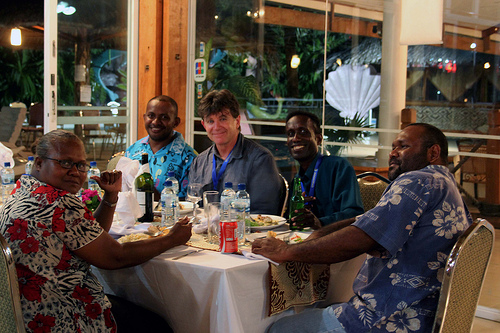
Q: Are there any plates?
A: Yes, there is a plate.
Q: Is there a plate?
A: Yes, there is a plate.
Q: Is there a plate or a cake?
A: Yes, there is a plate.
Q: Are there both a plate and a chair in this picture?
A: Yes, there are both a plate and a chair.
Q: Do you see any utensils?
A: No, there are no utensils.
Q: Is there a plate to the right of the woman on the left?
A: Yes, there is a plate to the right of the woman.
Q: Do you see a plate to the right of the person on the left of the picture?
A: Yes, there is a plate to the right of the woman.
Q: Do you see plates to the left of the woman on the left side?
A: No, the plate is to the right of the woman.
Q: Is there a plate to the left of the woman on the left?
A: No, the plate is to the right of the woman.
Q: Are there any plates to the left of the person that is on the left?
A: No, the plate is to the right of the woman.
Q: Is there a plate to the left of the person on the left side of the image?
A: No, the plate is to the right of the woman.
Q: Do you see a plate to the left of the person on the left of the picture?
A: No, the plate is to the right of the woman.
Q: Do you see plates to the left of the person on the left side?
A: No, the plate is to the right of the woman.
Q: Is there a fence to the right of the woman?
A: No, there is a plate to the right of the woman.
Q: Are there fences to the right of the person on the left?
A: No, there is a plate to the right of the woman.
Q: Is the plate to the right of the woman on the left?
A: Yes, the plate is to the right of the woman.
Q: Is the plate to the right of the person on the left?
A: Yes, the plate is to the right of the woman.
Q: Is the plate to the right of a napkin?
A: No, the plate is to the right of the woman.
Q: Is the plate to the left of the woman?
A: No, the plate is to the right of the woman.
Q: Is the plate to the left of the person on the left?
A: No, the plate is to the right of the woman.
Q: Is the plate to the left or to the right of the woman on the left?
A: The plate is to the right of the woman.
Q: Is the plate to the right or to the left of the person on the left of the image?
A: The plate is to the right of the woman.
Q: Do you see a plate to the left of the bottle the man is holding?
A: Yes, there is a plate to the left of the bottle.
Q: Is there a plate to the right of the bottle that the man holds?
A: No, the plate is to the left of the bottle.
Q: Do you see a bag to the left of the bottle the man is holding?
A: No, there is a plate to the left of the bottle.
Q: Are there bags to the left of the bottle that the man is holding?
A: No, there is a plate to the left of the bottle.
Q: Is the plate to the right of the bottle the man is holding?
A: No, the plate is to the left of the bottle.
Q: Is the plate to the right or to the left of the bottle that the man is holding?
A: The plate is to the left of the bottle.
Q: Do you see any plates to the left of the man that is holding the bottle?
A: Yes, there is a plate to the left of the man.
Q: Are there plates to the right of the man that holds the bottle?
A: No, the plate is to the left of the man.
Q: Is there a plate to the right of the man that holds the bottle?
A: No, the plate is to the left of the man.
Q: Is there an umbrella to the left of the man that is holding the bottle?
A: No, there is a plate to the left of the man.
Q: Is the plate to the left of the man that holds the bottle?
A: Yes, the plate is to the left of the man.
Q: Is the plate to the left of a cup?
A: No, the plate is to the left of the man.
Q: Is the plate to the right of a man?
A: No, the plate is to the left of a man.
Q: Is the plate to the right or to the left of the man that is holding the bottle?
A: The plate is to the left of the man.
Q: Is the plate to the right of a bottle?
A: Yes, the plate is to the right of a bottle.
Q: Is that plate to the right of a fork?
A: No, the plate is to the right of a bottle.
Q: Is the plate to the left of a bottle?
A: No, the plate is to the right of a bottle.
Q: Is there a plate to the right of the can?
A: Yes, there is a plate to the right of the can.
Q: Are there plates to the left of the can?
A: No, the plate is to the right of the can.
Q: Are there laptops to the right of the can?
A: No, there is a plate to the right of the can.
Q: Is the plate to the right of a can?
A: Yes, the plate is to the right of a can.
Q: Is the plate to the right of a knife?
A: No, the plate is to the right of a can.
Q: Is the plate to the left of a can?
A: No, the plate is to the right of a can.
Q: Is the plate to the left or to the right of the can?
A: The plate is to the right of the can.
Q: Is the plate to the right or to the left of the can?
A: The plate is to the right of the can.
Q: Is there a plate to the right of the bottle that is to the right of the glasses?
A: Yes, there is a plate to the right of the bottle.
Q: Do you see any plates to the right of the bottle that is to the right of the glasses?
A: Yes, there is a plate to the right of the bottle.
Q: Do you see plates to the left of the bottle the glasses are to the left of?
A: No, the plate is to the right of the bottle.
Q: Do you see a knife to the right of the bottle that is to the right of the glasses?
A: No, there is a plate to the right of the bottle.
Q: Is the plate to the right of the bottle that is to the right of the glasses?
A: Yes, the plate is to the right of the bottle.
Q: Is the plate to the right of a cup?
A: No, the plate is to the right of the bottle.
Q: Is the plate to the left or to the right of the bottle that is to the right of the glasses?
A: The plate is to the right of the bottle.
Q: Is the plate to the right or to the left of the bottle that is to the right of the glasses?
A: The plate is to the right of the bottle.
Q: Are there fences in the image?
A: No, there are no fences.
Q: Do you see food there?
A: Yes, there is food.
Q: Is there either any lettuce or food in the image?
A: Yes, there is food.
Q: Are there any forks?
A: No, there are no forks.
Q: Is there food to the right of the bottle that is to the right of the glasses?
A: Yes, there is food to the right of the bottle.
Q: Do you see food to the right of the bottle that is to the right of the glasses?
A: Yes, there is food to the right of the bottle.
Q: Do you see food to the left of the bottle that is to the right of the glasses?
A: No, the food is to the right of the bottle.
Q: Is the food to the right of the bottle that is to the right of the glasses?
A: Yes, the food is to the right of the bottle.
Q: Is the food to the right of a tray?
A: No, the food is to the right of the bottle.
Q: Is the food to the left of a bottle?
A: No, the food is to the right of a bottle.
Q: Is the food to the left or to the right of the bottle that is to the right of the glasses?
A: The food is to the right of the bottle.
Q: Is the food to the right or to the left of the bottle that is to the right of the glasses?
A: The food is to the right of the bottle.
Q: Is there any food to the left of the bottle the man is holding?
A: Yes, there is food to the left of the bottle.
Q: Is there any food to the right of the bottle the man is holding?
A: No, the food is to the left of the bottle.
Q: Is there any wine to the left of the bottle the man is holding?
A: No, there is food to the left of the bottle.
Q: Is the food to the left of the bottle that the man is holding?
A: Yes, the food is to the left of the bottle.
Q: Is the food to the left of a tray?
A: No, the food is to the left of the bottle.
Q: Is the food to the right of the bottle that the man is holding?
A: No, the food is to the left of the bottle.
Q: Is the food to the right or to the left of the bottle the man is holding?
A: The food is to the left of the bottle.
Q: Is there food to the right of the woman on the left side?
A: Yes, there is food to the right of the woman.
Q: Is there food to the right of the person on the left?
A: Yes, there is food to the right of the woman.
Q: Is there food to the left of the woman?
A: No, the food is to the right of the woman.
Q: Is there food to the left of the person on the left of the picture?
A: No, the food is to the right of the woman.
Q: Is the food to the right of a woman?
A: Yes, the food is to the right of a woman.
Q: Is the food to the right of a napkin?
A: No, the food is to the right of a woman.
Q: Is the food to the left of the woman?
A: No, the food is to the right of the woman.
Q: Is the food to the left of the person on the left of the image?
A: No, the food is to the right of the woman.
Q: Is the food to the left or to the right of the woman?
A: The food is to the right of the woman.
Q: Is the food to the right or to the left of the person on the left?
A: The food is to the right of the woman.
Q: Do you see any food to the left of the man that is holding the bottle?
A: Yes, there is food to the left of the man.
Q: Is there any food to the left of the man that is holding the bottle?
A: Yes, there is food to the left of the man.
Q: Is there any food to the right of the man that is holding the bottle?
A: No, the food is to the left of the man.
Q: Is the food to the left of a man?
A: Yes, the food is to the left of a man.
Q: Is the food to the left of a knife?
A: No, the food is to the left of a man.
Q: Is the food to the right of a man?
A: No, the food is to the left of a man.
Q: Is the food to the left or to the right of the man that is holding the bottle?
A: The food is to the left of the man.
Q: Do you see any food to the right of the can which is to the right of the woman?
A: Yes, there is food to the right of the can.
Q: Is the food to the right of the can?
A: Yes, the food is to the right of the can.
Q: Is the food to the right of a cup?
A: No, the food is to the right of the can.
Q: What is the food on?
A: The food is on the plate.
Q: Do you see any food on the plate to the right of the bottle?
A: Yes, there is food on the plate.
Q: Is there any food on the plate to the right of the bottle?
A: Yes, there is food on the plate.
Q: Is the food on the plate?
A: Yes, the food is on the plate.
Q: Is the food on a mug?
A: No, the food is on the plate.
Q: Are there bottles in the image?
A: Yes, there is a bottle.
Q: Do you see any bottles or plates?
A: Yes, there is a bottle.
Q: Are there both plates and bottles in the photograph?
A: Yes, there are both a bottle and a plate.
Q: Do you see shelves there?
A: No, there are no shelves.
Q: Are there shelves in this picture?
A: No, there are no shelves.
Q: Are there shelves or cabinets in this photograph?
A: No, there are no shelves or cabinets.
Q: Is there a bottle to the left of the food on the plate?
A: Yes, there is a bottle to the left of the food.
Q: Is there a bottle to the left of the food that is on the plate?
A: Yes, there is a bottle to the left of the food.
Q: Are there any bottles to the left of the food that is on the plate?
A: Yes, there is a bottle to the left of the food.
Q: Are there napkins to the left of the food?
A: No, there is a bottle to the left of the food.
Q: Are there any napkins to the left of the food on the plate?
A: No, there is a bottle to the left of the food.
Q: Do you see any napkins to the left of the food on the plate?
A: No, there is a bottle to the left of the food.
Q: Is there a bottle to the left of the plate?
A: Yes, there is a bottle to the left of the plate.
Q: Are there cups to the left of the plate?
A: No, there is a bottle to the left of the plate.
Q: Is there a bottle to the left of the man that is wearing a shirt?
A: Yes, there is a bottle to the left of the man.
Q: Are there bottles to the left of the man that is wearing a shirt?
A: Yes, there is a bottle to the left of the man.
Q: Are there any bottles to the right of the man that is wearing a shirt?
A: No, the bottle is to the left of the man.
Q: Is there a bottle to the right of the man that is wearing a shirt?
A: No, the bottle is to the left of the man.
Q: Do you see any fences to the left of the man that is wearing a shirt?
A: No, there is a bottle to the left of the man.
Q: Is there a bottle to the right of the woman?
A: Yes, there is a bottle to the right of the woman.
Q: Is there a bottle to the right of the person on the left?
A: Yes, there is a bottle to the right of the woman.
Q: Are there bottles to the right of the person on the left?
A: Yes, there is a bottle to the right of the woman.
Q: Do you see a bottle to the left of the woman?
A: No, the bottle is to the right of the woman.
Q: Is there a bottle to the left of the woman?
A: No, the bottle is to the right of the woman.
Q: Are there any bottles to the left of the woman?
A: No, the bottle is to the right of the woman.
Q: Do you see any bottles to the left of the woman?
A: No, the bottle is to the right of the woman.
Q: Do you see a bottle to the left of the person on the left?
A: No, the bottle is to the right of the woman.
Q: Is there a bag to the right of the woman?
A: No, there is a bottle to the right of the woman.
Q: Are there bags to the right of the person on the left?
A: No, there is a bottle to the right of the woman.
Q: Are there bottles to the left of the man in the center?
A: Yes, there is a bottle to the left of the man.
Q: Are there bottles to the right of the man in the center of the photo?
A: No, the bottle is to the left of the man.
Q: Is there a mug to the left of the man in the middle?
A: No, there is a bottle to the left of the man.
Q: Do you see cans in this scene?
A: Yes, there is a can.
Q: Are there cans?
A: Yes, there is a can.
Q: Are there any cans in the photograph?
A: Yes, there is a can.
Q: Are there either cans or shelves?
A: Yes, there is a can.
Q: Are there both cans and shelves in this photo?
A: No, there is a can but no shelves.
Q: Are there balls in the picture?
A: No, there are no balls.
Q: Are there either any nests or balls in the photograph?
A: No, there are no balls or nests.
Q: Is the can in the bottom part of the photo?
A: Yes, the can is in the bottom of the image.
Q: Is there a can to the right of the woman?
A: Yes, there is a can to the right of the woman.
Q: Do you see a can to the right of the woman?
A: Yes, there is a can to the right of the woman.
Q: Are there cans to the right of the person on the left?
A: Yes, there is a can to the right of the woman.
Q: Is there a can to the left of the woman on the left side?
A: No, the can is to the right of the woman.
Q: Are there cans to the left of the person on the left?
A: No, the can is to the right of the woman.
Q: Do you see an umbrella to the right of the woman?
A: No, there is a can to the right of the woman.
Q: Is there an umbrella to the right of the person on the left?
A: No, there is a can to the right of the woman.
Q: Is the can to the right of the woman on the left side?
A: Yes, the can is to the right of the woman.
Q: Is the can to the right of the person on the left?
A: Yes, the can is to the right of the woman.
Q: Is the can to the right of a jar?
A: No, the can is to the right of the woman.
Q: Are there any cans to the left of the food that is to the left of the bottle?
A: Yes, there is a can to the left of the food.